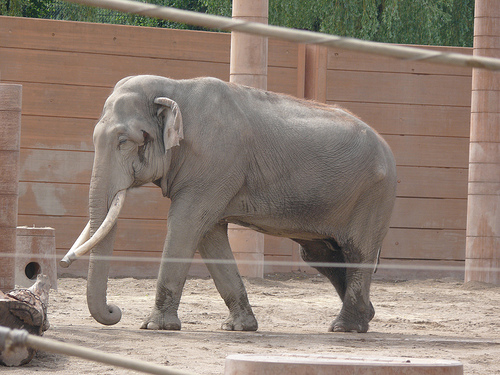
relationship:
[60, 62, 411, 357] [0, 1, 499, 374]
elephant in cage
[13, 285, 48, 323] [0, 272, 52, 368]
chain around log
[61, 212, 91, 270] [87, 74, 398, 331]
tusk of elephant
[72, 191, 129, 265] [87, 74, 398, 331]
tusk of elephant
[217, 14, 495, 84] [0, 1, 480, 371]
metal objects in cage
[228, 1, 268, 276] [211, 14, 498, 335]
support beam for structure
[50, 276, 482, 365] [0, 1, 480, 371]
dirt on bottom of cage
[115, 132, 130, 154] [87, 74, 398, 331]
eye of elephant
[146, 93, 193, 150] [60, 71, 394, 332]
ear of elephant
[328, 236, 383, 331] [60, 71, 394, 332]
back leg of elephant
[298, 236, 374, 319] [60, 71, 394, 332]
back leg of elephant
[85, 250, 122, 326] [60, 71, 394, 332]
trunk of elephant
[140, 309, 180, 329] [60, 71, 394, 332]
foot of elephant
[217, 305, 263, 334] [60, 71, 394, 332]
foot on elephant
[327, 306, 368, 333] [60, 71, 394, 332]
back foot on elephant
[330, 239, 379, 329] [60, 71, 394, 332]
back foot on elephant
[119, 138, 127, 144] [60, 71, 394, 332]
eye on elephant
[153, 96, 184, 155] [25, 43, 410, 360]
ear on elephant